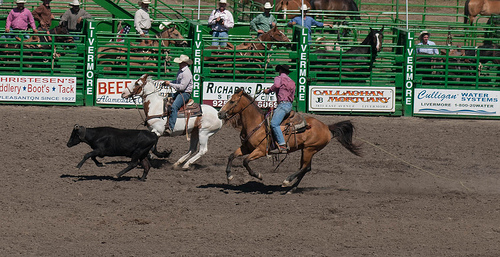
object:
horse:
[224, 82, 362, 210]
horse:
[20, 21, 64, 75]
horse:
[96, 33, 177, 75]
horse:
[213, 29, 293, 70]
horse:
[325, 30, 384, 80]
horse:
[424, 41, 489, 95]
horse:
[460, 3, 490, 31]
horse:
[292, 2, 397, 14]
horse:
[263, 1, 334, 28]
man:
[249, 55, 306, 202]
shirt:
[268, 69, 308, 100]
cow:
[64, 113, 155, 176]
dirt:
[355, 172, 410, 207]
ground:
[159, 156, 435, 237]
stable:
[30, 45, 421, 205]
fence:
[149, 1, 377, 91]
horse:
[106, 61, 208, 170]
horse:
[222, 90, 347, 180]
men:
[125, 10, 367, 48]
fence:
[107, 24, 416, 99]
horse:
[324, 31, 392, 91]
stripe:
[362, 22, 381, 51]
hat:
[165, 51, 217, 80]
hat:
[276, 61, 318, 79]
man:
[268, 57, 302, 145]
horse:
[224, 74, 330, 167]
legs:
[224, 145, 311, 188]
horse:
[213, 88, 363, 198]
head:
[214, 89, 252, 120]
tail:
[331, 120, 365, 155]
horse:
[220, 93, 369, 194]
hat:
[174, 52, 195, 63]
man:
[160, 51, 195, 131]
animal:
[64, 130, 174, 183]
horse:
[219, 87, 354, 193]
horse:
[122, 74, 225, 169]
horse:
[361, 25, 392, 55]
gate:
[303, 4, 414, 110]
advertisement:
[311, 84, 401, 117]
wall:
[9, 15, 483, 114]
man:
[167, 54, 193, 132]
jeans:
[163, 92, 190, 132]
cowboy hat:
[172, 50, 192, 62]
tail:
[331, 120, 361, 157]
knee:
[226, 153, 236, 162]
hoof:
[226, 170, 235, 187]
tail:
[151, 135, 174, 164]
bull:
[66, 120, 176, 180]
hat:
[273, 62, 289, 71]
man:
[263, 60, 294, 150]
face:
[371, 29, 382, 54]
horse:
[344, 20, 383, 78]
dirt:
[4, 105, 484, 254]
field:
[7, 102, 480, 252]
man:
[166, 58, 191, 131]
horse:
[125, 78, 225, 162]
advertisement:
[307, 80, 397, 111]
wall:
[304, 15, 409, 122]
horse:
[162, 47, 196, 139]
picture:
[4, 5, 498, 254]